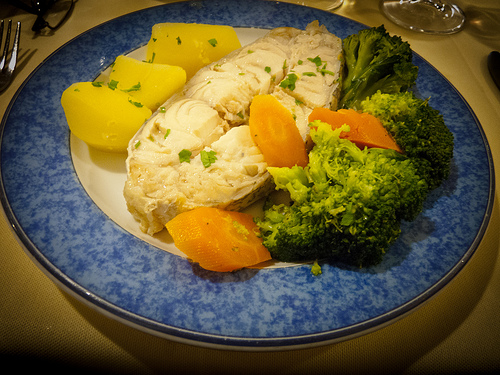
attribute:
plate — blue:
[7, 4, 492, 349]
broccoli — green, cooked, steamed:
[257, 22, 454, 273]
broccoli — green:
[299, 125, 434, 237]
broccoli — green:
[271, 117, 426, 262]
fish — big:
[136, 47, 331, 199]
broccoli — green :
[284, 110, 422, 268]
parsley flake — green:
[206, 32, 224, 52]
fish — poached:
[116, 35, 363, 245]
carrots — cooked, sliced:
[164, 89, 404, 276]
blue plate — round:
[0, 0, 497, 352]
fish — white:
[123, 16, 346, 238]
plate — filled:
[58, 20, 458, 268]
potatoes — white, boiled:
[92, 46, 182, 94]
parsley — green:
[84, 80, 178, 102]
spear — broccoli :
[335, 22, 415, 111]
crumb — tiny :
[308, 259, 323, 278]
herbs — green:
[91, 75, 146, 110]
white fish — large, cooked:
[187, 89, 251, 181]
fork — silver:
[1, 16, 19, 93]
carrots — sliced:
[187, 110, 404, 257]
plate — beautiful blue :
[26, 2, 499, 373]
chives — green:
[169, 152, 229, 197]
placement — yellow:
[7, 4, 492, 364]